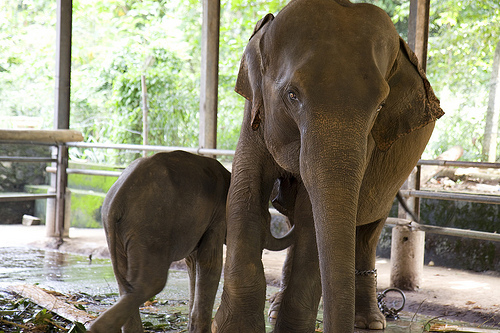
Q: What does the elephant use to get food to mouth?
A: Trunk.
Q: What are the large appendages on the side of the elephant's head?
A: Ears.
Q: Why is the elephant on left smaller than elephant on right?
A: It is a baby.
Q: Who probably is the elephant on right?
A: Baby elephant's mother.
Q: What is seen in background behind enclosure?
A: Trees.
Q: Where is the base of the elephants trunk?
A: Between eyes.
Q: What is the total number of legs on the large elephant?
A: 4.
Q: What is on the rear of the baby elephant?
A: Its tail.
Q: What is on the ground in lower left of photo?
A: Vegetation.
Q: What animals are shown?
A: Elephants.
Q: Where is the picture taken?
A: A zoo.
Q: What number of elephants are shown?
A: Two.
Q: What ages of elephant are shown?
A: Baby and adult.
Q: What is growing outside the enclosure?
A: Trees.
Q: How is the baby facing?
A: Away from camera.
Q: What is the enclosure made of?
A: Wood.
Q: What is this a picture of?
A: An open-walled enclosure with elephants in it, surrounded by vegetation.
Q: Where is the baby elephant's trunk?
A: Under the belly of the larger elephant.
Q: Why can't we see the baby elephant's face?
A: Because its head is under the mother elephant.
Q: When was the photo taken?
A: Day time.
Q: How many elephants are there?
A: Two.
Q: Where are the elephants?
A: The zoo.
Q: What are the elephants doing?
A: Standing.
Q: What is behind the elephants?
A: Trees.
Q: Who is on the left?
A: Baby elephant.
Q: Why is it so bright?
A: Sunny.